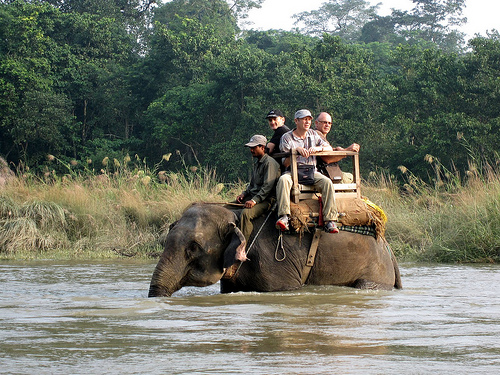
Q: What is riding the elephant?
A: Four men.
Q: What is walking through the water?
A: The elephant.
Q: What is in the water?
A: The elephants.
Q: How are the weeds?
A: Tall.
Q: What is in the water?
A: Elephant.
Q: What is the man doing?
A: Riding.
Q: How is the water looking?
A: Calm.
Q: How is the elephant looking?
A: Greenish.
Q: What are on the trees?
A: Leaves.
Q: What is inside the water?
A: Elephant.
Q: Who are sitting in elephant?
A: Passengers.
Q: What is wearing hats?
A: Three out of the four men.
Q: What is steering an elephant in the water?
A: The man.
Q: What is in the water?
A: The large elephant.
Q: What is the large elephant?
A: Wet.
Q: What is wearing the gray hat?
A: The man.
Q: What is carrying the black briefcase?
A: The man.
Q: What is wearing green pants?
A: The man.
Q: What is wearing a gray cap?
A: The man.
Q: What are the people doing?
A: Riding an elephant.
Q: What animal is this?
A: Elephant.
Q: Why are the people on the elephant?
A: Cross the river.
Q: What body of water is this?
A: River.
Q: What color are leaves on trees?
A: Green.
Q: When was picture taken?
A: Day time.